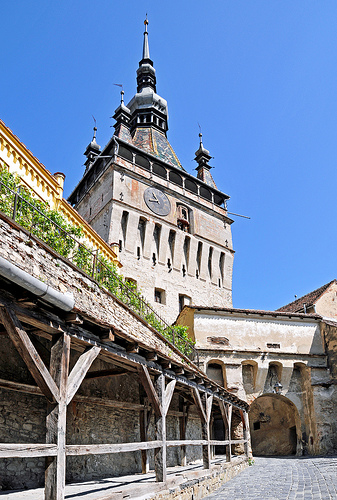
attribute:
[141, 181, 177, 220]
clock — black, grey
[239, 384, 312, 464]
entryway — arched, arch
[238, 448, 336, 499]
pathway — cobblestone, light gray, paved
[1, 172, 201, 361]
leaves — growing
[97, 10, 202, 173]
steeple — concrete, metal, decorative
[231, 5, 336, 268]
sky — blue, clear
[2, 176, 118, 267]
plants — green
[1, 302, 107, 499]
beam — vertical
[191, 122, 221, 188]
steeple — small, metal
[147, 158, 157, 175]
banister — worn looking, wooden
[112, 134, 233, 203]
beams — sturdy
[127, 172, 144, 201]
stain — rust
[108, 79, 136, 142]
spire — metal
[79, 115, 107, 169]
spire — metal